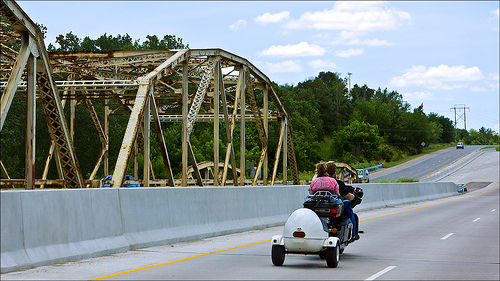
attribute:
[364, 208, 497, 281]
line — white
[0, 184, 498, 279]
road — large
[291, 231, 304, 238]
tail light — red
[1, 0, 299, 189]
bridge — metal, steel, old, rusted, small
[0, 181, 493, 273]
barrier — cement, concrete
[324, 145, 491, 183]
road — large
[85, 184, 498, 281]
line — yellow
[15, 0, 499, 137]
sky — cloudy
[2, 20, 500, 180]
trees — green, bushy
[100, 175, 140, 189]
car — blue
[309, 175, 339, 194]
shirt — pink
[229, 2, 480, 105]
clouds — white, fluffy